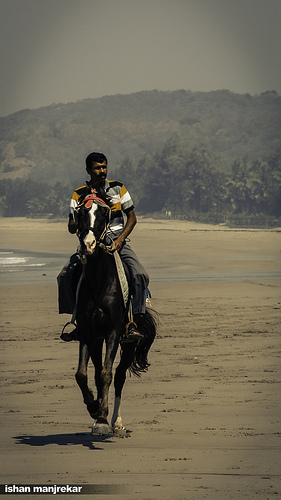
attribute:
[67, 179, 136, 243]
shirt — yellow, black, white, and grey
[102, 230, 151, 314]
pants — grey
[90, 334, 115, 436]
leg — brown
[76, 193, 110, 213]
headdress — red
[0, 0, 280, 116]
sky — grey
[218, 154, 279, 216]
bush — green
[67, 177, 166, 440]
horse — black and white